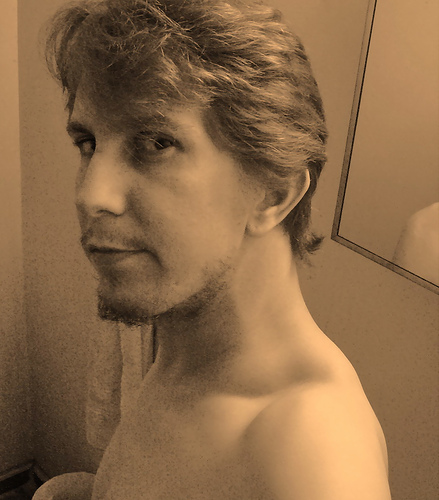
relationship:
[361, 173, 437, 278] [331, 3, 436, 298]
reflection in mirror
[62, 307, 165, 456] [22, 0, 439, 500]
curtain on on wall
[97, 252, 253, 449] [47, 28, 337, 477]
shadow on man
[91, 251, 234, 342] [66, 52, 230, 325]
beard on face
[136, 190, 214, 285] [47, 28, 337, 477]
jaw of man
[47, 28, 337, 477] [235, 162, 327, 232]
man has ear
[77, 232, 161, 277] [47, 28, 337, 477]
lips on man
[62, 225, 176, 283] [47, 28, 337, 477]
mouth on man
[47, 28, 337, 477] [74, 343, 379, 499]
man not wearing shirt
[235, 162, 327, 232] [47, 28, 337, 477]
ear on man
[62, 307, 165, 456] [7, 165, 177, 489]
towel hanging on wall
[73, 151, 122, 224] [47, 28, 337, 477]
nose on man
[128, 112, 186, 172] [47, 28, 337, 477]
eye on man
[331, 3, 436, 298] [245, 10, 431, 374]
mirror on wall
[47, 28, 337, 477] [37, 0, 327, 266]
man has blonde hair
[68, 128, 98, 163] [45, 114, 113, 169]
eye right eye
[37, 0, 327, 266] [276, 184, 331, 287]
blonde hair has tail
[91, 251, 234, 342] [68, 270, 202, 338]
beard on chin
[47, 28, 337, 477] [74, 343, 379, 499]
man wearing no shirt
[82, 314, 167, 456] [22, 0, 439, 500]
curtain on on wall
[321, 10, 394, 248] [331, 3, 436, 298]
metal on cabinet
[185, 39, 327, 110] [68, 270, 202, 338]
light on hair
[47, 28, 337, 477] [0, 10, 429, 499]
man in bathroom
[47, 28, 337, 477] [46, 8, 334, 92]
man has blonde hair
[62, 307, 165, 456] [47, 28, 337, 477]
curtain behind man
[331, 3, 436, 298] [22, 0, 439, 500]
mirror on on wall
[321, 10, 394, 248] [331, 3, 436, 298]
frame of mirror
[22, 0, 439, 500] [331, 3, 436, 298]
on wall reflection in mirror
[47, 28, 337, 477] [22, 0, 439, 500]
man taking on wall